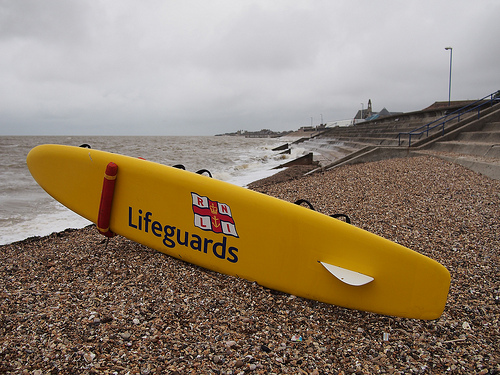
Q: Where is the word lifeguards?
A: Surfboard.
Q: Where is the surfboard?
A: In the gravels.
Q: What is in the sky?
A: Clouds.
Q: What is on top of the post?
A: Light.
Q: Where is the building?
A: Top right background.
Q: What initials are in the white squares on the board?
A: R N L I.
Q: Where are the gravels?
A: Shore.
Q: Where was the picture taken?
A: On a beach.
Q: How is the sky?
A: Overcast.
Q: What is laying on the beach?
A: A surfboard.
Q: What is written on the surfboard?
A: Lifeguards.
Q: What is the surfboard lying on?
A: Pebbles.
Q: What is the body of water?
A: The sea.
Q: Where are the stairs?
A: On the right.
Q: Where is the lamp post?
A: Behind the stairs.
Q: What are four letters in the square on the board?
A: R, L, H, I.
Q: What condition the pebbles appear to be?
A: Wet.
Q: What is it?
A: Surfboard.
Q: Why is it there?
A: To use.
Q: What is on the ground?
A: Pebbles.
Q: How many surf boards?
A: 1.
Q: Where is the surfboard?
A: On the ground.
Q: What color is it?
A: Yellow.